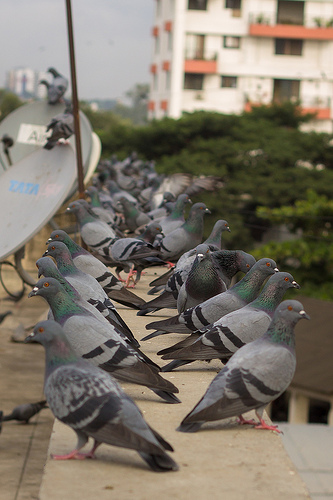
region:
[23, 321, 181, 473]
a grey black and green pigeon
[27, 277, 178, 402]
a grey black and green pigeon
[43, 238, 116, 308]
a grey black and green pigeon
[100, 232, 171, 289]
a grey black and green pigeon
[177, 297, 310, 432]
a grey black and green pigeon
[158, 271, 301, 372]
a grey black and green pigeon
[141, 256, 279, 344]
a grey black and green pigeon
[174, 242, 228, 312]
a grey black and green pigeon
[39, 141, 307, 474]
Pigeons roost above city buildings.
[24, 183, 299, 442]
Most birds facing opposite direction.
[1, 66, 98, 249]
Satellite disk attracts pigeons.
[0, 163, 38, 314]
Satellite dish anchored cement.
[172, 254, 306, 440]
Three birds row same markings.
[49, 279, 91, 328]
Neck coloring green, purple, black.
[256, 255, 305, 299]
Beady red eyes white stripe beak.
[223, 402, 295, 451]
Orange feet long claws.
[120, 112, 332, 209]
Trees full green leaves below.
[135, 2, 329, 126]
Hi-rise apartment tan orange complex.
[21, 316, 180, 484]
this is a bird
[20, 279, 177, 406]
this is a bird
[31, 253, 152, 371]
this is a bird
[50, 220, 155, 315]
this is a bird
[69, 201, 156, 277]
this is a bird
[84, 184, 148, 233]
this is a bird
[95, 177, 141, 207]
this is a bird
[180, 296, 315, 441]
this is a bird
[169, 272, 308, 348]
this is a bird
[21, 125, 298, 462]
rows of pigeons perched on ledge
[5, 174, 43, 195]
blue lettering on gray background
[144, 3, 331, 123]
white and orange building in background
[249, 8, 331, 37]
plants growing on balcony of building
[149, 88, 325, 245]
tops of green trees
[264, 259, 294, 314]
red eyes of three pigeons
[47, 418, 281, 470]
pink talons of two pigeons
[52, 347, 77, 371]
green coloring on pigeon's neck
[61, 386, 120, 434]
black stripes on pigeon's body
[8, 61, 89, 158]
pigeons perched on satellite dish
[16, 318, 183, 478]
Green and grey pigeon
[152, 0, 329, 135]
multi story building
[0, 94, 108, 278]
three satellite tv dishes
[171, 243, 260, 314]
pigeon cleaning itself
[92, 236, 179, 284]
pigeon eating off ledge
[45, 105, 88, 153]
bird on top of satellite dish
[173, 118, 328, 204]
green leaves on tree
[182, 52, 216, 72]
coral colored balcony on distant building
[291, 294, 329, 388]
brown roof top of building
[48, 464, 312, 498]
ledge on top of building